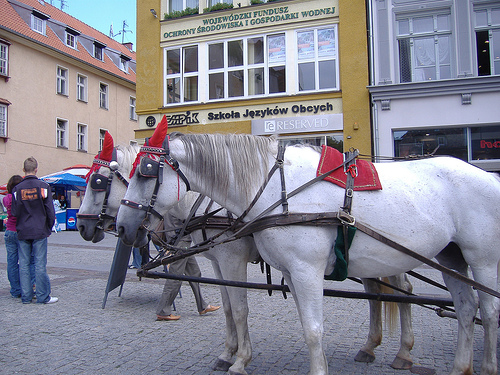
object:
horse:
[110, 111, 496, 366]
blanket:
[313, 142, 383, 192]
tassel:
[126, 115, 170, 186]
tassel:
[89, 128, 119, 184]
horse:
[70, 129, 422, 366]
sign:
[94, 202, 140, 316]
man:
[144, 232, 224, 323]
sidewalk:
[5, 221, 498, 365]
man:
[15, 155, 57, 309]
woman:
[1, 174, 21, 299]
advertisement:
[140, 100, 344, 130]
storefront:
[136, 101, 370, 171]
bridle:
[120, 134, 295, 276]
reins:
[291, 144, 377, 200]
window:
[153, 23, 341, 107]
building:
[134, 2, 370, 228]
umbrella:
[38, 164, 91, 192]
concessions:
[44, 200, 86, 230]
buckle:
[331, 210, 357, 229]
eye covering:
[137, 159, 161, 181]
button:
[146, 161, 152, 168]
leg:
[277, 246, 331, 373]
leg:
[227, 247, 251, 373]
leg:
[351, 269, 388, 365]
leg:
[470, 260, 496, 370]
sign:
[251, 115, 341, 142]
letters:
[267, 116, 329, 134]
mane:
[170, 124, 283, 207]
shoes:
[155, 303, 222, 325]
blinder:
[84, 176, 117, 192]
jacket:
[8, 178, 64, 240]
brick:
[371, 5, 497, 181]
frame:
[162, 25, 342, 110]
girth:
[325, 143, 361, 223]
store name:
[208, 101, 340, 125]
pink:
[3, 191, 22, 228]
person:
[157, 253, 218, 320]